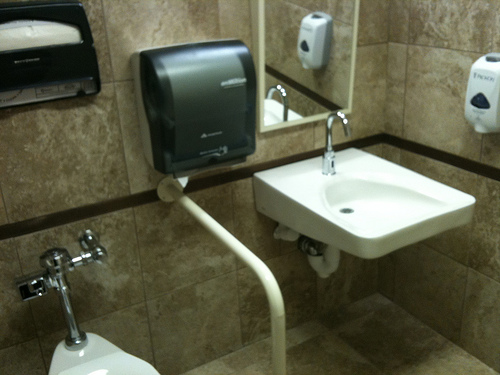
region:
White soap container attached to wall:
[460, 47, 496, 137]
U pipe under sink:
[306, 232, 346, 280]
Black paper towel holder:
[122, 31, 267, 181]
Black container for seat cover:
[0, 0, 108, 120]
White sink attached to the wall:
[246, 143, 477, 259]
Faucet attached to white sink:
[315, 105, 351, 170]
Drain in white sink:
[333, 198, 359, 218]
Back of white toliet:
[27, 322, 157, 372]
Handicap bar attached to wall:
[152, 176, 305, 369]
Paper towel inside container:
[157, 47, 249, 97]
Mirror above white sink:
[254, 0, 356, 137]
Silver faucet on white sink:
[321, 110, 351, 172]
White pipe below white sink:
[272, 219, 342, 284]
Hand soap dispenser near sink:
[463, 46, 498, 142]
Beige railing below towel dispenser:
[158, 177, 288, 374]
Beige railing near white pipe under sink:
[154, 172, 290, 373]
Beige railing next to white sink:
[155, 177, 291, 374]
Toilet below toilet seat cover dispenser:
[15, 229, 170, 374]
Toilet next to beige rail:
[16, 222, 173, 374]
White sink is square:
[249, 141, 476, 260]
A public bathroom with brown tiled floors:
[40, 57, 475, 334]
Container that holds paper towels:
[110, 40, 255, 200]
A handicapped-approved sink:
[276, 97, 441, 272]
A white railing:
[156, 192, 351, 372]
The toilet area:
[22, 240, 155, 371]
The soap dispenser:
[445, 47, 497, 127]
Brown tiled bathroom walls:
[10, 115, 222, 341]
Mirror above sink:
[220, 0, 360, 120]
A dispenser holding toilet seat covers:
[10, 15, 120, 100]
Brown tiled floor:
[325, 320, 427, 371]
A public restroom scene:
[9, 3, 492, 370]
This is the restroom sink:
[255, 110, 475, 260]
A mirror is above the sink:
[255, 0, 365, 170]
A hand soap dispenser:
[460, 45, 495, 140]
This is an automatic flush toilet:
[12, 230, 167, 370]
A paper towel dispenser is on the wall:
[130, 30, 260, 176]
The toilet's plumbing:
[14, 225, 112, 350]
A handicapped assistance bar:
[151, 175, 306, 374]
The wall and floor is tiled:
[421, 237, 497, 374]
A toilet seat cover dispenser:
[0, 1, 105, 117]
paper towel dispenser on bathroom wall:
[130, 32, 265, 184]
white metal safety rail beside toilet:
[167, 188, 271, 370]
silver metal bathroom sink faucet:
[312, 99, 356, 180]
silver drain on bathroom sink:
[329, 201, 354, 222]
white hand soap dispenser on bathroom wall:
[443, 42, 498, 145]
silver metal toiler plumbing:
[11, 232, 115, 339]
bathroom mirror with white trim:
[251, 0, 363, 132]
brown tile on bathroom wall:
[139, 252, 229, 342]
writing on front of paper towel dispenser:
[204, 72, 252, 87]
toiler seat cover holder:
[0, 0, 110, 103]